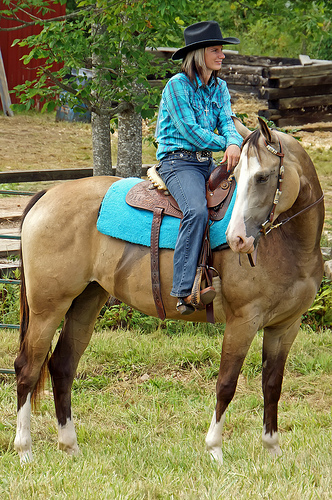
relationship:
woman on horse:
[166, 20, 229, 313] [25, 137, 318, 376]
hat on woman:
[176, 22, 262, 49] [166, 20, 229, 313]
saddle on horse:
[126, 175, 258, 218] [25, 137, 318, 376]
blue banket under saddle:
[102, 200, 130, 249] [126, 175, 258, 218]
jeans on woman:
[163, 162, 201, 226] [166, 20, 229, 313]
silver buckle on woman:
[191, 156, 205, 164] [166, 20, 229, 313]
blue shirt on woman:
[170, 71, 223, 184] [166, 20, 229, 313]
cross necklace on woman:
[191, 95, 215, 126] [166, 20, 229, 313]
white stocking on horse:
[22, 406, 40, 453] [25, 137, 318, 376]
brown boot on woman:
[162, 288, 198, 324] [166, 20, 229, 313]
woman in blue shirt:
[166, 20, 229, 313] [170, 71, 223, 184]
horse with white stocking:
[25, 137, 318, 376] [22, 406, 40, 453]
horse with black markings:
[25, 137, 318, 376] [265, 353, 279, 424]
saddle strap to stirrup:
[207, 151, 221, 196] [183, 246, 239, 306]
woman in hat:
[166, 20, 229, 313] [176, 22, 262, 49]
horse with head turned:
[25, 137, 318, 376] [236, 136, 331, 300]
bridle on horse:
[276, 177, 313, 237] [25, 137, 318, 376]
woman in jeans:
[166, 20, 229, 313] [163, 162, 201, 226]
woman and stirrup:
[166, 20, 229, 313] [183, 246, 239, 306]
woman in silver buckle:
[166, 20, 229, 313] [191, 156, 205, 164]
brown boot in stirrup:
[162, 288, 198, 324] [183, 246, 239, 306]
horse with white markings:
[25, 137, 318, 376] [236, 147, 270, 239]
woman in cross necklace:
[166, 20, 229, 313] [191, 95, 215, 126]